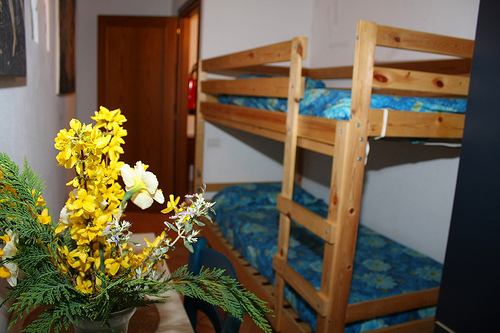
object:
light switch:
[205, 135, 227, 145]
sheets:
[214, 182, 450, 327]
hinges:
[170, 22, 185, 39]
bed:
[203, 20, 473, 158]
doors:
[90, 3, 206, 214]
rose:
[118, 157, 165, 212]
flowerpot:
[48, 297, 139, 330]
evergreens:
[1, 151, 273, 330]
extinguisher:
[189, 76, 195, 113]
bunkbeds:
[199, 20, 480, 332]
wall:
[201, 2, 483, 265]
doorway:
[177, 4, 198, 199]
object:
[181, 68, 201, 139]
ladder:
[272, 20, 362, 332]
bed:
[201, 179, 456, 333]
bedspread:
[212, 185, 444, 330]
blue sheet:
[217, 175, 439, 326]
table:
[123, 229, 196, 330]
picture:
[57, 0, 82, 100]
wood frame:
[2, 0, 29, 90]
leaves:
[168, 275, 254, 307]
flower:
[24, 104, 180, 300]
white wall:
[0, 92, 61, 140]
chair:
[174, 232, 250, 332]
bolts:
[350, 120, 369, 161]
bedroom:
[0, 0, 499, 330]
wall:
[3, 2, 81, 251]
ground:
[173, 239, 238, 311]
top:
[204, 13, 474, 138]